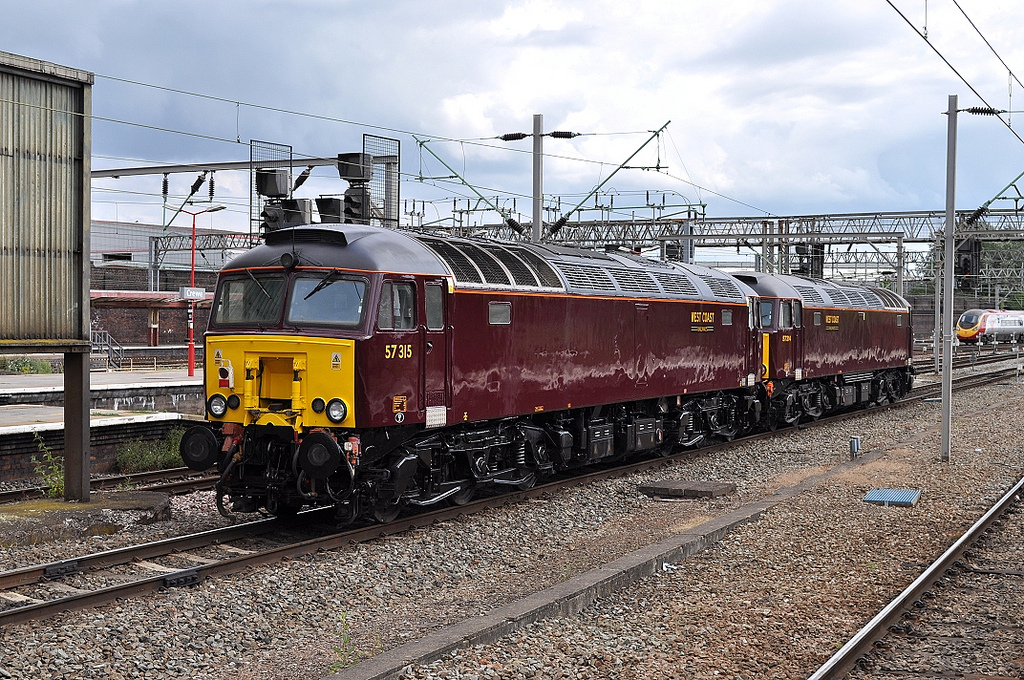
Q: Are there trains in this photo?
A: Yes, there is a train.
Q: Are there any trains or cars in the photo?
A: Yes, there is a train.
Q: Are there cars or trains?
A: Yes, there is a train.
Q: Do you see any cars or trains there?
A: Yes, there is a train.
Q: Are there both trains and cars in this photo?
A: No, there is a train but no cars.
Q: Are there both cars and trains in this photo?
A: No, there is a train but no cars.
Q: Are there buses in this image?
A: No, there are no buses.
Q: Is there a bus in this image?
A: No, there are no buses.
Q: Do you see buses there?
A: No, there are no buses.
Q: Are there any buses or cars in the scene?
A: No, there are no buses or cars.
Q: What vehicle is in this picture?
A: The vehicle is a train.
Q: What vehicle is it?
A: The vehicle is a train.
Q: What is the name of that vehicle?
A: This is a train.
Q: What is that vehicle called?
A: This is a train.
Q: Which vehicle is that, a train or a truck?
A: This is a train.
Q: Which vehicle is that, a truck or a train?
A: This is a train.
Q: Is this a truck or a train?
A: This is a train.